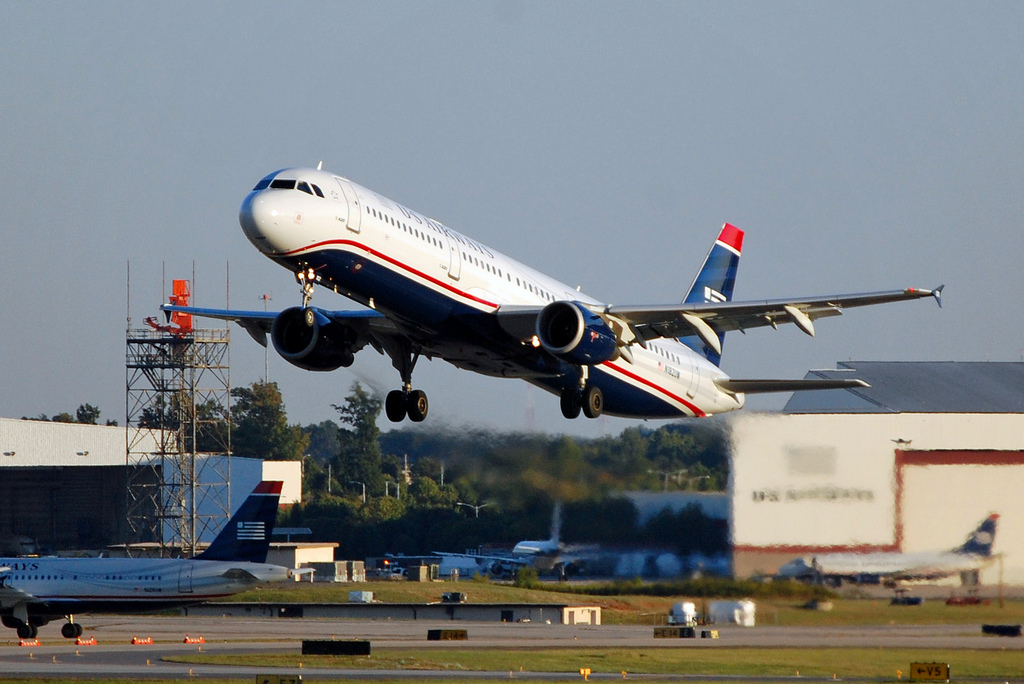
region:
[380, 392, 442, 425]
wheel attached on airplane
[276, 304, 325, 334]
wheels attached on airplane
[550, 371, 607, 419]
wheels attached to plane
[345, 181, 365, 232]
door closed on the plane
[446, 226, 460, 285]
door closed on plane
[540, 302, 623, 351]
engine attached to plane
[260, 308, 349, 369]
engine attached to plane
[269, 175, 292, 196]
window attached on plane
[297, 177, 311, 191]
window attached on plane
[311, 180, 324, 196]
window attached on plane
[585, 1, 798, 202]
grey and blue sky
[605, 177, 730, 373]
blue and red tail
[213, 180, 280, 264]
white nose of plane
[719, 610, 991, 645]
runway is dark grey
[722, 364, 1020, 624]
white building in distance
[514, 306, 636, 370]
engines are dark blue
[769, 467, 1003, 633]
plane next to hangar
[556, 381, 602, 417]
wheel attached to plane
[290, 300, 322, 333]
wheel attached to plane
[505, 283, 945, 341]
wing attached to plane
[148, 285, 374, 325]
wing attached to plane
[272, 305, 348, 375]
engine attached to wing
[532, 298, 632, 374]
engine attached to wing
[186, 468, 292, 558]
tail wing attached to plane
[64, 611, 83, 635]
wheel attached to plane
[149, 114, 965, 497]
Plane taking off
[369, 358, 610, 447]
Airplane landing gear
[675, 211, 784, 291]
Red and blue tail wing on plane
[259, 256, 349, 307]
Landing gear at front of plane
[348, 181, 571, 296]
Passenger windows on plane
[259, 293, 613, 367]
Engines on each side of plane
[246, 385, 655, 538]
Trees on the other side of airport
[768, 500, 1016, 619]
A plane on ground behind plane in the air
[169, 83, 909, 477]
white plane in air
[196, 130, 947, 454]
red white and blue plane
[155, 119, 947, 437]
red white and blue plane in air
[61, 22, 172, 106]
white clouds in blue sky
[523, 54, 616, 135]
white clouds in blue sky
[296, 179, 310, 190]
The windows on a plane.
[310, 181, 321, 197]
The windows on a plane.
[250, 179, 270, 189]
The windows on a plane.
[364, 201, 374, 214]
The windows on a plane.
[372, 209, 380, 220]
The windows on a plane.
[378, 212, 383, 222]
The windows on a plane.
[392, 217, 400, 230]
The windows on a plane.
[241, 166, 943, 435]
a large white airplane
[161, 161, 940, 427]
a large red and blue plane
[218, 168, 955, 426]
a large airplane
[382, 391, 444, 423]
the tire on the airplane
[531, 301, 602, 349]
the propeller on the plane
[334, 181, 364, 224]
a door on the airplane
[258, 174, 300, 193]
the windshield on the airplane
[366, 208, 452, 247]
windows on the airplane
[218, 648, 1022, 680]
grass under the airplane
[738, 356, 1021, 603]
a building behind the airplane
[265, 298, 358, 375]
part of jet airplane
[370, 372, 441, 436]
part of jet airplane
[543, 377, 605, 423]
part of jet airplane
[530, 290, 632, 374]
part of jet airplane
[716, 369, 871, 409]
part of jet airplane